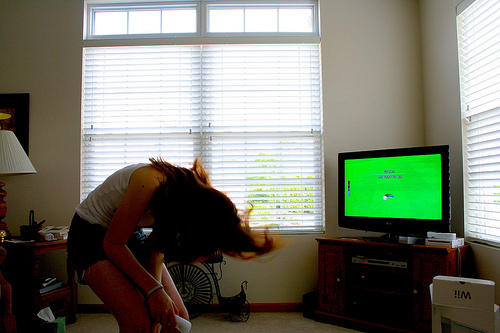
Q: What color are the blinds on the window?
A: White.